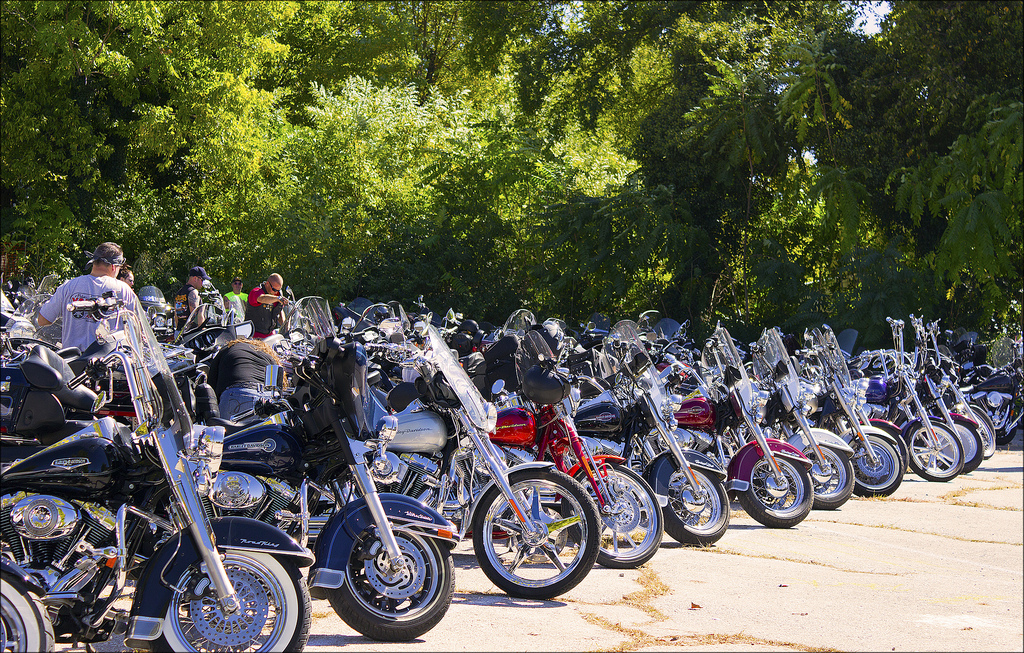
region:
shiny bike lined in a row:
[13, 293, 314, 649]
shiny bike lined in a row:
[228, 328, 459, 623]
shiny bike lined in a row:
[411, 309, 599, 589]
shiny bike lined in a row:
[622, 306, 820, 541]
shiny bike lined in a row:
[755, 319, 934, 515]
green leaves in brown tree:
[732, 160, 794, 217]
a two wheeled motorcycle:
[11, 273, 334, 647]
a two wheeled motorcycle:
[142, 301, 446, 643]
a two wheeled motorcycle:
[566, 329, 735, 554]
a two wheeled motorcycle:
[638, 346, 819, 536]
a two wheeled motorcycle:
[853, 319, 964, 485]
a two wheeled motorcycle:
[900, 310, 995, 460]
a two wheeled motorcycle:
[957, 351, 1022, 446]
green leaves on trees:
[0, 2, 1018, 317]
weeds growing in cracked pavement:
[380, 450, 1022, 650]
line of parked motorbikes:
[0, 308, 991, 642]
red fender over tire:
[731, 435, 812, 525]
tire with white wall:
[155, 551, 307, 650]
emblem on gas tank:
[3, 435, 124, 496]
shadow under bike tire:
[313, 537, 454, 648]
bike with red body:
[490, 382, 659, 564]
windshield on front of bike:
[414, 325, 491, 433]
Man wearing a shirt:
[244, 279, 290, 349]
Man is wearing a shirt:
[247, 269, 292, 339]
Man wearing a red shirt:
[239, 273, 291, 341]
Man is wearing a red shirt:
[239, 277, 287, 332]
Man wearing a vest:
[235, 272, 292, 334]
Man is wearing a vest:
[234, 269, 285, 340]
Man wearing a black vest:
[244, 280, 290, 338]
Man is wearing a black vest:
[239, 276, 290, 338]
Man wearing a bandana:
[81, 241, 127, 270]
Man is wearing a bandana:
[83, 239, 129, 271]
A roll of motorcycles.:
[13, 298, 1015, 647]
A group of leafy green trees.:
[19, 1, 1010, 246]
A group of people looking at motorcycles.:
[47, 236, 308, 345]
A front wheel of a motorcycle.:
[307, 494, 457, 632]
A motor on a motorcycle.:
[4, 495, 115, 597]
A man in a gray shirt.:
[36, 242, 164, 359]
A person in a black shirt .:
[205, 337, 283, 423]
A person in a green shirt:
[226, 281, 250, 311]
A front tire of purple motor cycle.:
[733, 434, 817, 533]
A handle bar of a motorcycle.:
[61, 352, 138, 397]